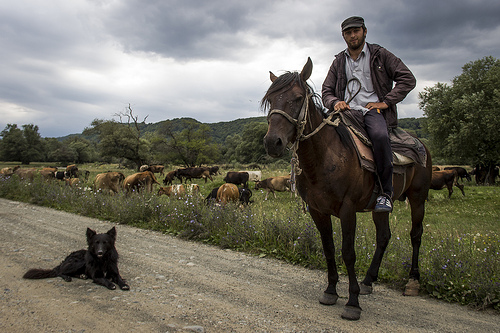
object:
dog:
[21, 225, 129, 291]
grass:
[440, 197, 484, 224]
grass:
[130, 188, 240, 228]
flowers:
[188, 201, 196, 206]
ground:
[0, 162, 499, 331]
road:
[0, 196, 499, 330]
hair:
[258, 67, 301, 115]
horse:
[258, 56, 433, 321]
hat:
[338, 15, 363, 31]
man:
[319, 15, 417, 214]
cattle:
[157, 182, 205, 203]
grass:
[10, 158, 82, 204]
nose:
[261, 136, 285, 160]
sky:
[0, 0, 499, 138]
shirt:
[341, 43, 383, 119]